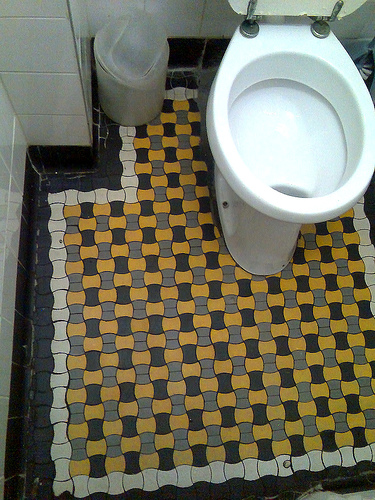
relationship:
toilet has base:
[196, 17, 364, 279] [205, 151, 310, 298]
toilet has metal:
[196, 17, 364, 279] [237, 8, 343, 49]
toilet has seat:
[196, 17, 364, 279] [204, 28, 373, 217]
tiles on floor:
[41, 242, 91, 369] [8, 150, 351, 499]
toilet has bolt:
[196, 17, 364, 279] [209, 191, 231, 219]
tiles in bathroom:
[41, 242, 91, 369] [4, 13, 368, 499]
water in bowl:
[249, 97, 318, 173] [196, 127, 323, 234]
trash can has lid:
[84, 6, 168, 130] [106, 26, 162, 77]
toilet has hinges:
[196, 17, 364, 279] [240, 8, 354, 25]